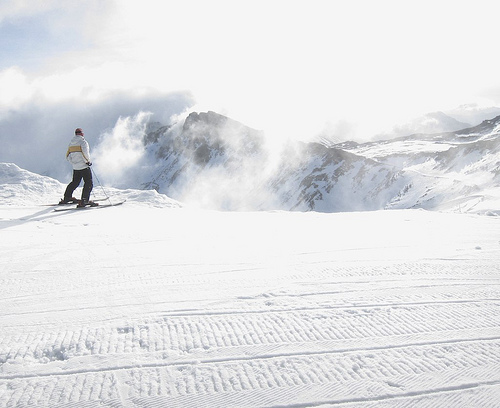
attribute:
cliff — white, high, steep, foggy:
[133, 178, 253, 270]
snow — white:
[164, 226, 342, 323]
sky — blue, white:
[38, 15, 112, 96]